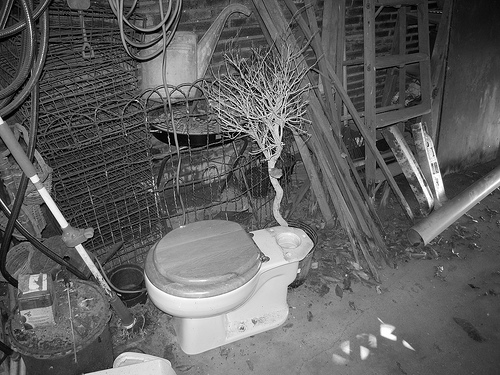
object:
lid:
[152, 216, 261, 288]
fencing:
[37, 77, 291, 291]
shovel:
[68, 2, 93, 60]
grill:
[133, 96, 264, 205]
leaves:
[433, 242, 488, 265]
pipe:
[406, 166, 500, 249]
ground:
[22, 170, 498, 372]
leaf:
[335, 285, 343, 298]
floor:
[2, 162, 497, 373]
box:
[17, 272, 59, 331]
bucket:
[1, 272, 112, 373]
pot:
[275, 231, 304, 250]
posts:
[244, 2, 414, 284]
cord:
[109, 0, 182, 61]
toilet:
[139, 215, 316, 355]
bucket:
[104, 264, 149, 308]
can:
[131, 3, 250, 97]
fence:
[55, 92, 205, 223]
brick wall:
[2, 1, 500, 231]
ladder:
[319, 0, 439, 193]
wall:
[0, 2, 495, 283]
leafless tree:
[198, 24, 308, 230]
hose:
[0, 2, 52, 280]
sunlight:
[324, 315, 416, 365]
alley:
[4, 0, 500, 375]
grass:
[218, 94, 294, 173]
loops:
[84, 103, 173, 181]